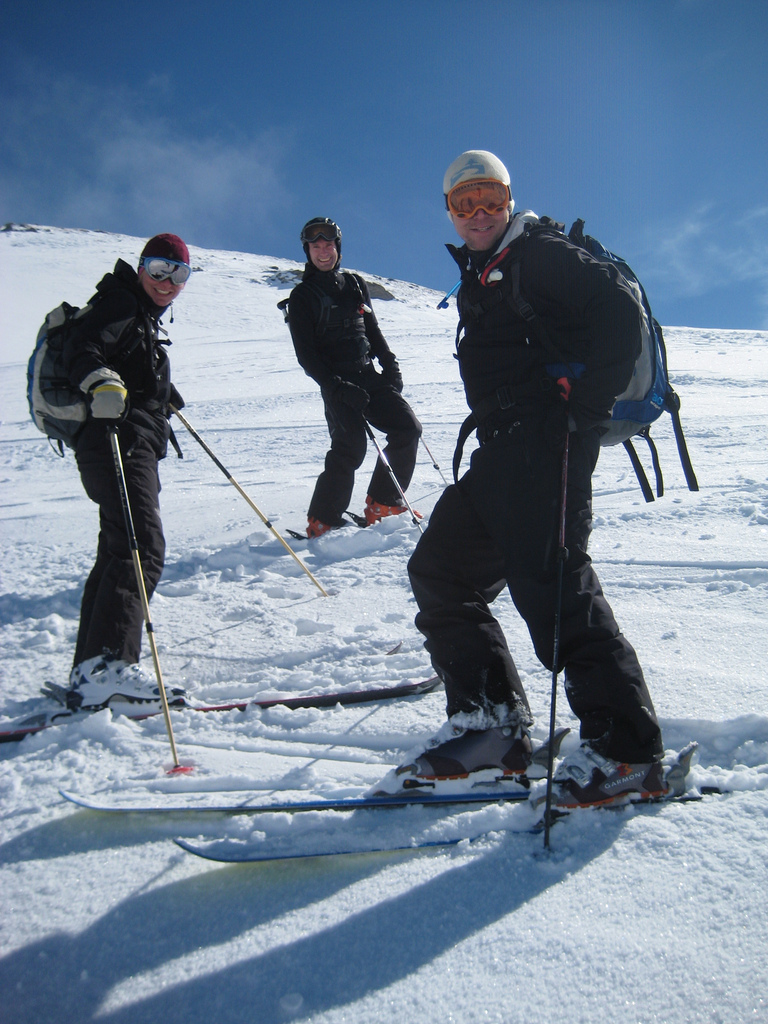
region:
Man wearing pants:
[66, 446, 182, 672]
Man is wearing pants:
[65, 432, 180, 672]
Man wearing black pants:
[57, 436, 176, 669]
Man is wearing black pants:
[58, 426, 188, 670]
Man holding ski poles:
[74, 364, 355, 780]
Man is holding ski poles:
[86, 368, 348, 783]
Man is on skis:
[29, 749, 742, 885]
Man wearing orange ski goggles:
[434, 170, 521, 220]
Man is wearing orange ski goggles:
[437, 164, 525, 222]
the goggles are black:
[298, 220, 339, 241]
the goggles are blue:
[140, 252, 192, 284]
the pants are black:
[407, 416, 667, 764]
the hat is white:
[444, 147, 514, 219]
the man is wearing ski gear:
[1, 233, 440, 777]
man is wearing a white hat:
[437, 143, 512, 186]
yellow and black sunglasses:
[430, 172, 526, 218]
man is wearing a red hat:
[143, 228, 196, 264]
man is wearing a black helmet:
[292, 210, 349, 240]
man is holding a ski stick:
[94, 403, 201, 780]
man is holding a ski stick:
[157, 382, 345, 602]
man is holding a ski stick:
[325, 349, 441, 535]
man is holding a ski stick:
[376, 358, 459, 488]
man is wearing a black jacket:
[431, 223, 644, 439]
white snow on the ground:
[365, 852, 524, 993]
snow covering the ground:
[429, 824, 581, 979]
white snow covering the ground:
[561, 930, 681, 1022]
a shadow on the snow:
[161, 748, 455, 1010]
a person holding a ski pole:
[68, 384, 209, 828]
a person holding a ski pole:
[505, 364, 575, 878]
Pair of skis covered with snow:
[54, 768, 743, 864]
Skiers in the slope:
[0, 146, 759, 865]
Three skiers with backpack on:
[22, 147, 704, 820]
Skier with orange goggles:
[366, 144, 700, 816]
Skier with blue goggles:
[22, 230, 195, 712]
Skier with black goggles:
[283, 214, 425, 543]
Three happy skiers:
[24, 147, 705, 815]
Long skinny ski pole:
[533, 437, 579, 857]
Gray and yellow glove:
[87, 377, 127, 420]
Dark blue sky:
[2, 2, 766, 327]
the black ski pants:
[63, 405, 169, 667]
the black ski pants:
[312, 368, 411, 518]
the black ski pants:
[403, 421, 671, 756]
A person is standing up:
[414, 147, 693, 805]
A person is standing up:
[257, 207, 431, 535]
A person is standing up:
[396, 143, 694, 828]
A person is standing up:
[252, 201, 486, 530]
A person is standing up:
[9, 228, 243, 740]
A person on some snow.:
[32, 221, 240, 728]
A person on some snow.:
[241, 188, 385, 534]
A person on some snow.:
[383, 89, 732, 801]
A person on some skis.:
[379, 95, 699, 810]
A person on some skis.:
[263, 173, 439, 539]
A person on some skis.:
[15, 199, 232, 733]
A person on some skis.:
[214, 161, 420, 526]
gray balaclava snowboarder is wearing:
[441, 145, 509, 202]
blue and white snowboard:
[65, 761, 712, 855]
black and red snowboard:
[10, 663, 440, 739]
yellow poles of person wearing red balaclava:
[103, 368, 333, 773]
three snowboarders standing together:
[30, 132, 694, 823]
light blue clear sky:
[8, 2, 765, 331]